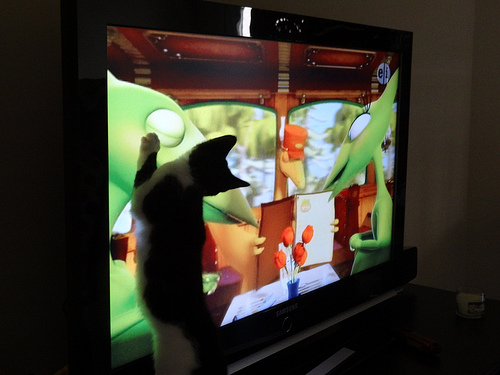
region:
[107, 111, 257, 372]
black and white cat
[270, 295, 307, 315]
company name on front of television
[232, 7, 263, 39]
light reflection on television frame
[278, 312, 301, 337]
black remote sensor on front of television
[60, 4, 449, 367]
cat leaning on flat screen television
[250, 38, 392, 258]
image on television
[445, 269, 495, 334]
small container sitting on table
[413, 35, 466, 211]
white paint on wall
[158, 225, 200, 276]
black fur on cat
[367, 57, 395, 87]
channel logo on screen of television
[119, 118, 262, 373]
a cat stand on a TV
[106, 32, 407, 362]
a cat watching TV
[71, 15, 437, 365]
a flat screen TV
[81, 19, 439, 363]
a flat screen color TV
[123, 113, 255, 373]
cat color is white and black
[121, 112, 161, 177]
paw of cat is white and black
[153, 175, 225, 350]
back of cat is black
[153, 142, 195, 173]
front neck of cat is white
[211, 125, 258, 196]
pointy ears of cat are black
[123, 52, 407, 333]
a cartoon on TV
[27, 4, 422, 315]
the tv is big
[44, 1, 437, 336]
the tv is on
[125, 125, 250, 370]
the cat is touching the tv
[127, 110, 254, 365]
the cat is black and white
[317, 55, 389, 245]
a green character on the tv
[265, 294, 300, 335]
the power button on the tv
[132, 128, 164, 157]
cats paw is white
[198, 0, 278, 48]
light reflecting off of tv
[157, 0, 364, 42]
the tv frame is shiny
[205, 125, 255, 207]
the cats ears are black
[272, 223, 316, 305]
Vase with orange tulips in it.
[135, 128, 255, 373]
Cat trying to get the characters in the TV.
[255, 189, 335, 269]
Menu that the bird is looking at.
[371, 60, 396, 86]
The TV stations logo.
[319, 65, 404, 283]
Green Jurassic looking char.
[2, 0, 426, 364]
Big black flat screen TV.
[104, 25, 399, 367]
A kids cartoon TV show on the TV.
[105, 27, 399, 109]
The roof of the train that the cartoon characters are ridding in.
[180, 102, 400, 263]
Window of train looking out into the cartoon world.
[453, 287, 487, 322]
Jar of something sitting by the TV.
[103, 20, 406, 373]
THE TV IS ON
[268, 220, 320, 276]
THE TULIPS ARE RED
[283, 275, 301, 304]
THE VASE IS BLUE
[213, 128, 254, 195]
THE CAT HAS BLACK EARS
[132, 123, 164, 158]
THE CAT'S PAW IS WHITE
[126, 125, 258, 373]
THE CAT IS BLACK AND WHITE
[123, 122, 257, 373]
THE CAT IS FURRY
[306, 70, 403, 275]
THE DINOSAUR IS GREEN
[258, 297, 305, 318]
THE TELEVISION IS A SAMSUNG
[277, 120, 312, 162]
THE DINOSAUR IS WEARING A HAT